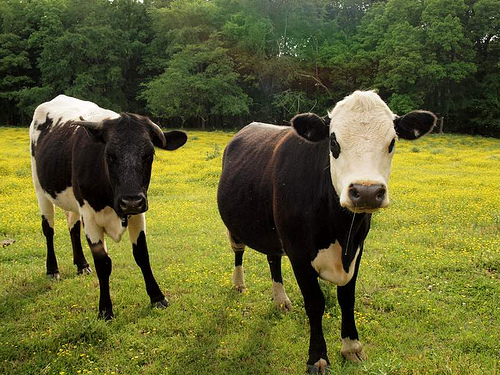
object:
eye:
[385, 137, 400, 154]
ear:
[395, 108, 441, 141]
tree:
[0, 5, 46, 127]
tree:
[137, 5, 259, 133]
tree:
[362, 5, 484, 138]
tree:
[63, 53, 137, 123]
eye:
[104, 151, 119, 166]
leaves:
[382, 25, 397, 37]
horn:
[69, 122, 105, 141]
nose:
[346, 180, 387, 212]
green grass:
[407, 269, 500, 375]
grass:
[1, 122, 498, 374]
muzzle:
[115, 193, 150, 218]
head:
[76, 115, 191, 219]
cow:
[25, 90, 190, 318]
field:
[4, 89, 494, 368]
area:
[2, 5, 497, 132]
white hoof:
[272, 296, 293, 312]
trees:
[266, 67, 334, 128]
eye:
[328, 131, 341, 158]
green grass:
[85, 313, 292, 363]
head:
[291, 88, 438, 217]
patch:
[431, 161, 468, 183]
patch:
[419, 209, 464, 246]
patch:
[186, 225, 216, 282]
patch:
[395, 279, 465, 356]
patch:
[28, 309, 111, 349]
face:
[326, 90, 398, 215]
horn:
[140, 111, 170, 151]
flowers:
[490, 243, 499, 252]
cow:
[215, 81, 435, 373]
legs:
[295, 252, 339, 373]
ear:
[156, 125, 190, 153]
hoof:
[147, 297, 171, 310]